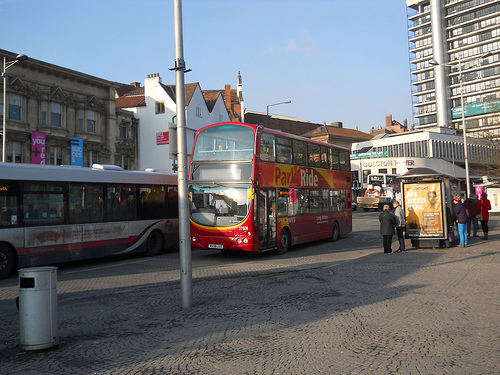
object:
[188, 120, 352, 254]
bus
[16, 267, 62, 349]
trashcan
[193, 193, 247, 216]
window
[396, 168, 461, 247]
bus stop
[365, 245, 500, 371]
sidewalk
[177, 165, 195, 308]
pole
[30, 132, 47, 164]
banner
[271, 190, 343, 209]
windows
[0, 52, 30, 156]
streetlight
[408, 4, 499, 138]
building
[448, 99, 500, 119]
sign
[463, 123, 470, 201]
pole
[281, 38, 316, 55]
cloud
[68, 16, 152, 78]
sky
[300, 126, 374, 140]
roof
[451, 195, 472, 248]
people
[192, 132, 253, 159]
window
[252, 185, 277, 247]
door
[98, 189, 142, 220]
people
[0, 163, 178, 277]
bus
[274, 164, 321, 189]
billboard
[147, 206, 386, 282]
road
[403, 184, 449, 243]
sign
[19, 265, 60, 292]
lid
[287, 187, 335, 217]
people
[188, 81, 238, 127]
roof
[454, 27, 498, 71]
balconies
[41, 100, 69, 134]
window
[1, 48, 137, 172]
building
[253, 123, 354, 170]
top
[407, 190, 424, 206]
writing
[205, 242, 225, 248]
license plate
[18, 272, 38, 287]
opening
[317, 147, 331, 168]
window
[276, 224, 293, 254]
tire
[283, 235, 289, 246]
black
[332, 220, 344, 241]
tire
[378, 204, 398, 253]
person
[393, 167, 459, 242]
side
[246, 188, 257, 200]
mirror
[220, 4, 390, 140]
sky